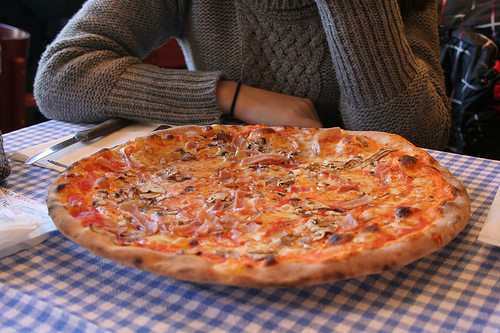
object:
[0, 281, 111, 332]
wrinkle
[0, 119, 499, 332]
table cloth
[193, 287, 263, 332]
lines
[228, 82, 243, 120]
tie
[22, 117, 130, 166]
knife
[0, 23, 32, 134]
chair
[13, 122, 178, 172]
paper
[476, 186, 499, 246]
napkin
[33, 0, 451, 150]
sweater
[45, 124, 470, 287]
pizza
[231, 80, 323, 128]
hand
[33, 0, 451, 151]
person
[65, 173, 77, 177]
dark spot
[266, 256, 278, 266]
dark spot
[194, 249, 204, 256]
dark spot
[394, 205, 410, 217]
dark spot